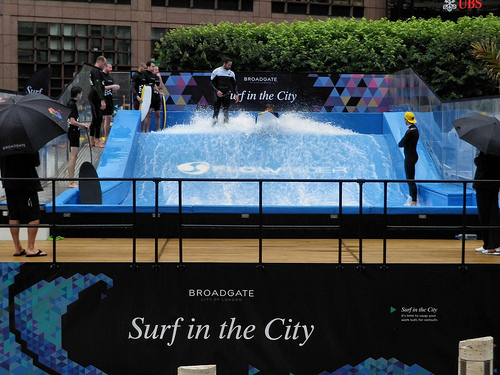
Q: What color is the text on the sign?
A: White.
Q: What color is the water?
A: Blue.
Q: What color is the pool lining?
A: Blue.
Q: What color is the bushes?
A: Green.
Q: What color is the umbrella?
A: Black.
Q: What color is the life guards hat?
A: Yellow.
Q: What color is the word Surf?
A: White.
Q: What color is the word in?
A: White.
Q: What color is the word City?
A: White.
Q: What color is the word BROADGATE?
A: White.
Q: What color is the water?
A: Blue.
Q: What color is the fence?
A: Black.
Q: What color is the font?
A: White.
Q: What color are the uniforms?
A: Black.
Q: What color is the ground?
A: Brown.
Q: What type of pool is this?
A: Surfing.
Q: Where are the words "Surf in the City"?
A: Bottom of page and sign behind pool.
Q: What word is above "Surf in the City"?
A: Broadgate.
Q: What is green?
A: Bushes.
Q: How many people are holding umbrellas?
A: Two.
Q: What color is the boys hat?
A: Yellow.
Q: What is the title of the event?
A: Surf in the city.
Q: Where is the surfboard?
A: In the water.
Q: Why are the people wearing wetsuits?
A: Surfing.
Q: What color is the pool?
A: Blue.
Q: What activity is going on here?
A: Surfing.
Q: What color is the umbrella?
A: Black.